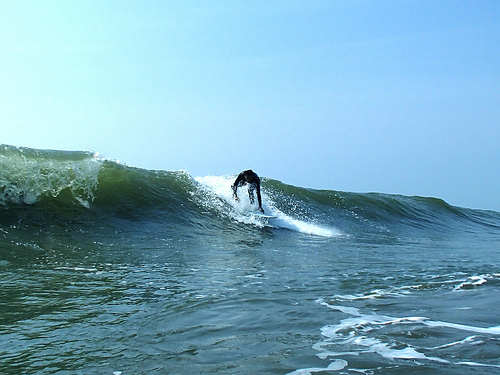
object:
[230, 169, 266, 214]
man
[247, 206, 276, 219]
surfboard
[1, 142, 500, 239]
wave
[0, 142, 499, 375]
water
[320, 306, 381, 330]
foam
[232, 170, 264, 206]
wetsuit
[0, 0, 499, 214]
sky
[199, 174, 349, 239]
splash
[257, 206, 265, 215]
hand